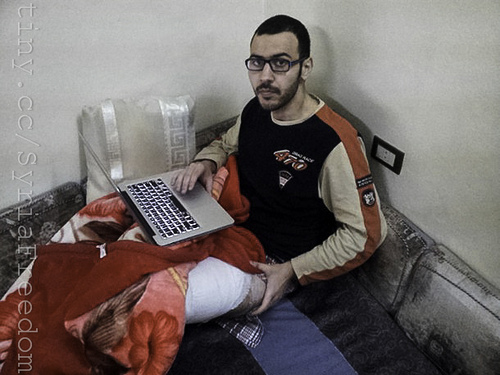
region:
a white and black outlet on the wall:
[363, 128, 418, 175]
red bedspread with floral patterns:
[1, 247, 191, 372]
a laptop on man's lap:
[69, 123, 246, 248]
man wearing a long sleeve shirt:
[206, 94, 386, 286]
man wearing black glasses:
[230, 49, 318, 79]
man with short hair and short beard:
[238, 4, 315, 113]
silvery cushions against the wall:
[371, 206, 497, 369]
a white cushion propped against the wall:
[76, 92, 210, 191]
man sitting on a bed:
[66, 16, 394, 352]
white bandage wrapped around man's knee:
[190, 254, 262, 326]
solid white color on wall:
[100, 23, 205, 63]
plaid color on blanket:
[212, 315, 274, 346]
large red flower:
[46, 309, 193, 357]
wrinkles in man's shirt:
[294, 229, 382, 279]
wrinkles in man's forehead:
[238, 37, 292, 53]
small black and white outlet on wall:
[358, 125, 421, 173]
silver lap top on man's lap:
[76, 140, 232, 249]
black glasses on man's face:
[233, 50, 308, 79]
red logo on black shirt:
[261, 144, 323, 186]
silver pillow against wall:
[57, 78, 209, 192]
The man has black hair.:
[252, 13, 314, 50]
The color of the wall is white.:
[345, 14, 492, 116]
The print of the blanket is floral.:
[15, 191, 235, 341]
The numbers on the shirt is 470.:
[265, 136, 319, 175]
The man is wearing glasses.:
[245, 52, 297, 75]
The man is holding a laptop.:
[77, 132, 237, 249]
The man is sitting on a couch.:
[142, 125, 489, 373]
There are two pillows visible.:
[350, 172, 498, 346]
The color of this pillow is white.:
[85, 101, 195, 165]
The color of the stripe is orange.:
[315, 98, 383, 294]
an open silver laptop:
[77, 130, 235, 242]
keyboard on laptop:
[127, 176, 200, 244]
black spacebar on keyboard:
[169, 192, 188, 214]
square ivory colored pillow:
[78, 94, 200, 206]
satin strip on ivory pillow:
[99, 99, 124, 189]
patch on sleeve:
[361, 190, 376, 206]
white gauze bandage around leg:
[186, 256, 246, 325]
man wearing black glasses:
[244, 54, 304, 75]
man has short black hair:
[251, 14, 310, 61]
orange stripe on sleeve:
[297, 104, 382, 294]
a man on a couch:
[61, 10, 493, 335]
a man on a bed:
[72, 24, 444, 364]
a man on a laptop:
[55, 0, 425, 372]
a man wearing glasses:
[84, 20, 498, 366]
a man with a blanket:
[64, 24, 497, 366]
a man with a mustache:
[128, 16, 456, 321]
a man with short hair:
[123, 5, 497, 303]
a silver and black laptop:
[57, 97, 253, 274]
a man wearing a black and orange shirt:
[126, 46, 461, 356]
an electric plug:
[334, 82, 461, 262]